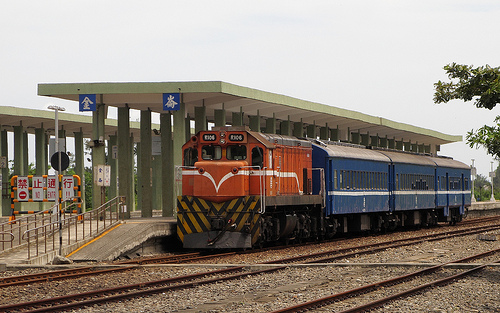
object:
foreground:
[0, 248, 499, 311]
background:
[0, 160, 499, 201]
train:
[176, 129, 473, 249]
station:
[0, 81, 464, 269]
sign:
[162, 93, 180, 111]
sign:
[78, 94, 98, 111]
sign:
[95, 164, 112, 187]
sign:
[16, 176, 75, 201]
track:
[0, 218, 498, 312]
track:
[268, 248, 498, 311]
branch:
[443, 62, 500, 81]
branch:
[464, 125, 498, 157]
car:
[310, 138, 393, 216]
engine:
[178, 126, 273, 248]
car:
[373, 146, 435, 212]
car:
[424, 153, 470, 207]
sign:
[203, 134, 216, 141]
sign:
[229, 134, 245, 141]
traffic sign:
[50, 151, 70, 171]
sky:
[0, 1, 499, 178]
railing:
[22, 196, 121, 261]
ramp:
[1, 220, 147, 264]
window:
[203, 145, 222, 159]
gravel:
[408, 293, 499, 312]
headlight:
[198, 167, 206, 174]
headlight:
[231, 167, 238, 174]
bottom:
[175, 204, 468, 249]